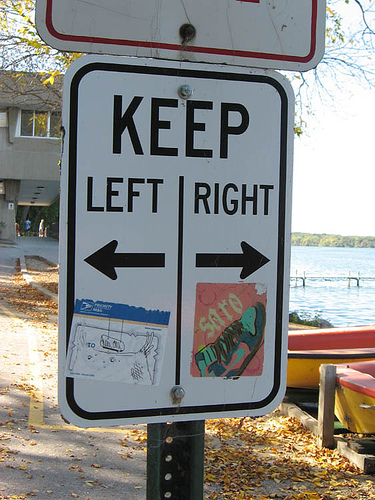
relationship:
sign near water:
[42, 41, 304, 422] [289, 242, 373, 341]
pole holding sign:
[137, 423, 216, 498] [42, 41, 304, 422]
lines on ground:
[5, 286, 63, 439] [9, 240, 344, 500]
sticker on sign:
[180, 273, 277, 391] [42, 41, 304, 422]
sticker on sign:
[62, 288, 172, 402] [42, 41, 304, 422]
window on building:
[15, 112, 72, 146] [2, 60, 79, 256]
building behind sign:
[2, 60, 79, 256] [42, 41, 304, 422]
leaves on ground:
[202, 411, 360, 497] [9, 240, 344, 500]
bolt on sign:
[168, 377, 191, 408] [42, 41, 304, 422]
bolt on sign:
[173, 80, 197, 105] [42, 41, 304, 422]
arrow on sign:
[189, 241, 274, 284] [42, 41, 304, 422]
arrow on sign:
[82, 230, 176, 285] [42, 41, 304, 422]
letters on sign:
[84, 88, 281, 233] [42, 41, 304, 422]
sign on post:
[42, 41, 304, 422] [137, 423, 216, 498]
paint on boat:
[286, 352, 370, 387] [291, 321, 373, 385]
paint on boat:
[288, 327, 374, 357] [291, 321, 373, 385]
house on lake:
[2, 60, 79, 256] [289, 242, 373, 341]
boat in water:
[291, 321, 373, 385] [289, 242, 373, 341]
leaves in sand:
[22, 254, 61, 303] [26, 254, 63, 303]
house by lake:
[2, 60, 79, 256] [289, 242, 373, 341]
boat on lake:
[291, 321, 373, 385] [289, 242, 373, 341]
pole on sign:
[137, 423, 216, 498] [42, 41, 304, 422]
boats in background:
[275, 319, 371, 426] [10, 8, 373, 283]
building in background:
[2, 60, 79, 256] [10, 8, 373, 283]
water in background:
[289, 242, 373, 341] [10, 8, 373, 283]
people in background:
[21, 210, 36, 243] [10, 8, 373, 283]